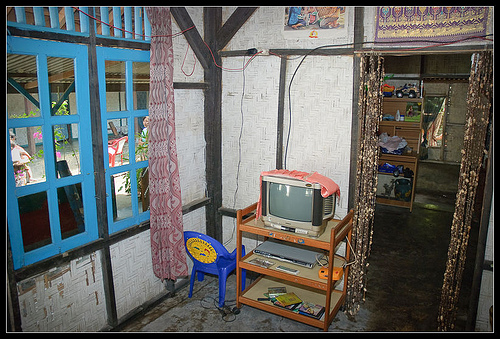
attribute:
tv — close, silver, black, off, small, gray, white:
[258, 163, 333, 240]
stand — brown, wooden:
[241, 224, 345, 328]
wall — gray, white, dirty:
[256, 54, 347, 153]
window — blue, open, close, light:
[12, 36, 162, 250]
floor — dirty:
[166, 287, 220, 329]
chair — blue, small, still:
[166, 232, 226, 305]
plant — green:
[13, 96, 69, 176]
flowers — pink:
[32, 130, 61, 159]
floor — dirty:
[119, 198, 453, 335]